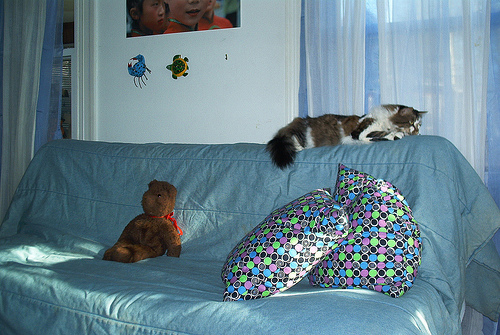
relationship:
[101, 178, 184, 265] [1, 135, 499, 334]
teddy bear on couch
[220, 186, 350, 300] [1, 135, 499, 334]
pillow on couch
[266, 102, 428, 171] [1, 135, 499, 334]
cat laying on couch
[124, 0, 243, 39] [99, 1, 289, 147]
picture on wall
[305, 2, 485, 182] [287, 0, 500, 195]
curtains on window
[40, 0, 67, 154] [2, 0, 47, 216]
curtain behind curtain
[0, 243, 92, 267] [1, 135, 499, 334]
sunlight on couch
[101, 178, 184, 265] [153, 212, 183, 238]
teddy bear wearing ribbon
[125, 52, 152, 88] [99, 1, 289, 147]
crab on wall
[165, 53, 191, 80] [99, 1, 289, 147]
turtle on wall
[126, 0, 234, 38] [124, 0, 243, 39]
kids on picture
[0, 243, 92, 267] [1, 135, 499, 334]
sunlight shining on couch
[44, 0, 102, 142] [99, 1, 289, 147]
window on wall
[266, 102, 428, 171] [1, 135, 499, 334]
cat on couch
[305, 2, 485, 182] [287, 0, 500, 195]
curtains over window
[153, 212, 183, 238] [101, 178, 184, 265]
ribbon on teddy bear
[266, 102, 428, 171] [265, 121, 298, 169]
cat has tail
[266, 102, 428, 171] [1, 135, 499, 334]
cat resting on couch